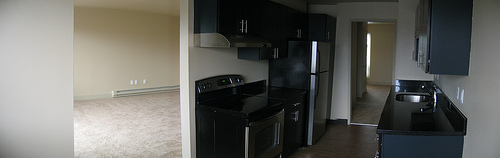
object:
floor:
[278, 123, 378, 156]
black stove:
[193, 75, 314, 157]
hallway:
[349, 18, 392, 125]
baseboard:
[108, 75, 185, 102]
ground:
[460, 97, 495, 125]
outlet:
[130, 79, 133, 84]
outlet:
[135, 80, 138, 85]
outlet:
[143, 79, 147, 84]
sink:
[394, 93, 431, 102]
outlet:
[453, 86, 465, 103]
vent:
[201, 32, 278, 52]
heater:
[107, 85, 184, 98]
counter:
[374, 79, 466, 158]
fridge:
[267, 37, 333, 147]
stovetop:
[199, 84, 306, 117]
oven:
[241, 115, 298, 158]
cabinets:
[218, 0, 299, 45]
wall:
[76, 0, 178, 108]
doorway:
[350, 18, 386, 82]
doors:
[215, 7, 271, 42]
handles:
[308, 37, 316, 140]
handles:
[272, 48, 279, 59]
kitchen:
[191, 0, 500, 158]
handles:
[240, 19, 248, 33]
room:
[2, 0, 499, 158]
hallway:
[353, 42, 387, 111]